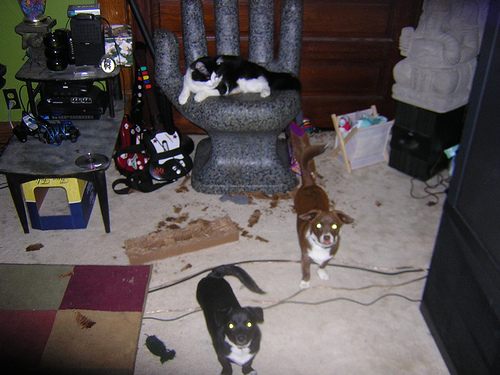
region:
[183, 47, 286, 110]
black and white cat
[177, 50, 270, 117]
cat sitting on hand chair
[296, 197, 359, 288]
brown and white dog with glowing eyes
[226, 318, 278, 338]
dog has glowing eyes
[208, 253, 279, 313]
dog has thick tail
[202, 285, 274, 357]
dog is black and white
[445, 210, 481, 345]
black big screen television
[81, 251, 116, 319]
burgundy square on rug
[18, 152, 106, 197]
gray coffee table with black legs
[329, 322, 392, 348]
gray carpet by chair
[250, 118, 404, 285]
A dog standing in a living room.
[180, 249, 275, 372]
A dog standing near a destroyed area.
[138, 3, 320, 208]
a cat resting in a giant hand.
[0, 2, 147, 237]
a multi level table.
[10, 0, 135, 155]
clutter on a multi level table.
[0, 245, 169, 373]
a multi colored square rug.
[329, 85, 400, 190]
a small toy container.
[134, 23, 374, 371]
a group of bratty animals.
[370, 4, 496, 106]
a large soft item.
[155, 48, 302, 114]
a cat n a toy.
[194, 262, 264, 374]
A black and white dog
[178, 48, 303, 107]
A black and white cat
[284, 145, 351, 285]
A white and brown dog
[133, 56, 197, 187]
A guitar hero controller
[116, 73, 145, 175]
A guitar hero controller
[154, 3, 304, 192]
A hand-shaped chair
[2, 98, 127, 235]
A grey and black table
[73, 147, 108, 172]
A disc on the table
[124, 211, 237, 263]
A piece of cardboard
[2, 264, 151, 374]
A multi colored rug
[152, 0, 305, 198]
the hand shaped chair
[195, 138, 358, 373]
the two dogs on the ground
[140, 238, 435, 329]
the wires going across the floor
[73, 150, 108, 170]
a compact disc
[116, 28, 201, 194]
standing guitar video game controllers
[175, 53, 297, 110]
the black and white cat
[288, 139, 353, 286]
the brown and white dog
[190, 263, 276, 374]
the black and white dog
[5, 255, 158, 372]
a corner of a colorful area rug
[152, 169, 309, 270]
dog poop all over the floor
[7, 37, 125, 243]
gray colored double table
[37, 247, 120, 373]
colorful area rug with poop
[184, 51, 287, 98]
cat sittin in a chair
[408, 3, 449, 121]
white buddha on speaker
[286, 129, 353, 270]
brown and white dog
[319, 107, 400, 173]
small wood and material tote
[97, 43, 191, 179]
two guitar hero guitars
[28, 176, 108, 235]
blue and yellow litter box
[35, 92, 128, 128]
black stereo system on table